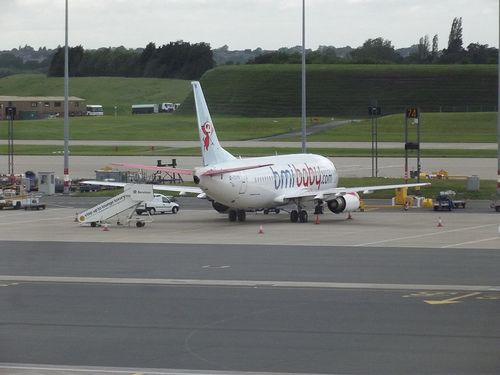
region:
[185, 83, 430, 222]
Large white plane on a tarmac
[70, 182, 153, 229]
White mobile stairway behind a plane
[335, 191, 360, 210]
White covered engine on a plane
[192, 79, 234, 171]
White tail of a plane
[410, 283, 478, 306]
Yellow mark on a runway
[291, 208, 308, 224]
Two landing wheels beneath a plane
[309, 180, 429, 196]
White wing on a plane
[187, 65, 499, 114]
Landscaped green hill beside an airport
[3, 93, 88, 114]
Low tan building at airport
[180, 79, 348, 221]
red and white plane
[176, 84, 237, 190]
red and white tail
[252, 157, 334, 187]
grey and white name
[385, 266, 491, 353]
yellow arrow on tarmac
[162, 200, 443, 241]
orange cones around plane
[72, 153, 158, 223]
white ladder near plane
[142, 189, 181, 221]
white van behind ladder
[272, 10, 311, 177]
grey poles behind plane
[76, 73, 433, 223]
a jet with two wings.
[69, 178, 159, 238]
an airplane stairway.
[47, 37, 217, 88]
a forest of green trees.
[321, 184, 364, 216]
a jet engine on a wing.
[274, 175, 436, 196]
a right wing on a jet.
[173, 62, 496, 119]
a tall green hedge.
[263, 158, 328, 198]
writing on the side of a plane.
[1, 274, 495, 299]
a line painted on a road.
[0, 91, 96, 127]
a building near an airport.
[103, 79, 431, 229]
Plane on the ground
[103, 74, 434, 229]
Plane is on the ground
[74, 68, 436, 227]
Airplane on the ground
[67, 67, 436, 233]
Airplane is on the ground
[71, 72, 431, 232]
White plane on the ground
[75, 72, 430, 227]
White plane is on the ground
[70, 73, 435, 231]
White airplane on the ground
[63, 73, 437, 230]
White airplane is on the ground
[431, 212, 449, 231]
Orange cones on the ground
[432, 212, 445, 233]
Orange cones are on the ground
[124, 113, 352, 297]
a plane on the ground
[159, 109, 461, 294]
an airplane on the ground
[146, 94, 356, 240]
a large plane on the ground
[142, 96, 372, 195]
a large airplane on the ground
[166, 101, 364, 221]
a passenger plane in the ground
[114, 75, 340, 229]
a passenger airplane on the ground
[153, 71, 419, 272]
a white plane on the ground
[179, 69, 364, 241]
a white airplane on the ground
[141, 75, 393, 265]
a large white airplane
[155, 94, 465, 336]
a large white plane